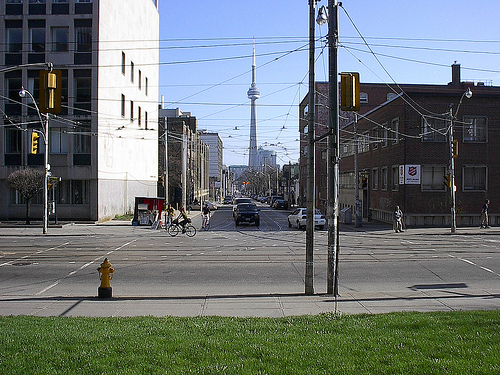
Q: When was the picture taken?
A: Daytime.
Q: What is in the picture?
A: Cars.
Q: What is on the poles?
A: Traffic lights.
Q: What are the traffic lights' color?
A: Yellow.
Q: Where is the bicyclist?
A: Crossing the street.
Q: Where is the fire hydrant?
A: On the curb.